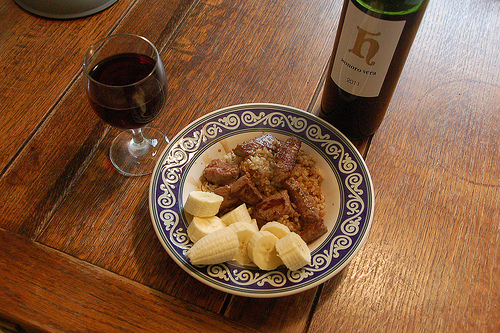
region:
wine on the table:
[335, 3, 417, 136]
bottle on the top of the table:
[338, 8, 437, 146]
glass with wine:
[73, 24, 165, 178]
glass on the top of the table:
[66, 33, 173, 179]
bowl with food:
[157, 109, 367, 299]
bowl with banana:
[166, 85, 364, 326]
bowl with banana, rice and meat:
[183, 99, 371, 295]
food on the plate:
[161, 89, 364, 309]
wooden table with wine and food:
[3, 8, 497, 328]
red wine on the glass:
[70, 36, 185, 185]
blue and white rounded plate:
[161, 108, 376, 308]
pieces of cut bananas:
[167, 202, 309, 275]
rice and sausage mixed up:
[217, 131, 334, 218]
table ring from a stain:
[442, 67, 498, 229]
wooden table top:
[380, 180, 456, 273]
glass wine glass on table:
[68, 40, 167, 197]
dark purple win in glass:
[74, 77, 198, 126]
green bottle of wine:
[333, 0, 391, 146]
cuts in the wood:
[22, 200, 105, 263]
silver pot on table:
[16, 7, 116, 27]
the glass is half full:
[78, 47, 180, 138]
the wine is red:
[71, 40, 188, 148]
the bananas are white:
[172, 175, 309, 271]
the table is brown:
[410, 152, 475, 305]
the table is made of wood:
[418, 140, 485, 278]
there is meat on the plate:
[213, 145, 322, 214]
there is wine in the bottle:
[332, 6, 414, 123]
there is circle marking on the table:
[418, 69, 484, 203]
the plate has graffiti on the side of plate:
[172, 105, 377, 291]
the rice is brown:
[229, 138, 323, 209]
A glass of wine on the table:
[70, 33, 182, 180]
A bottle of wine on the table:
[316, 0, 429, 135]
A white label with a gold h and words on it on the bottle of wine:
[327, 3, 405, 111]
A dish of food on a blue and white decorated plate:
[150, 98, 378, 312]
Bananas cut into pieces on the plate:
[182, 190, 312, 275]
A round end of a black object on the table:
[0, 0, 140, 32]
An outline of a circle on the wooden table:
[408, 60, 498, 191]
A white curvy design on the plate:
[206, 106, 311, 138]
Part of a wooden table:
[0, 18, 90, 330]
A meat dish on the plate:
[211, 136, 331, 217]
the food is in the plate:
[156, 100, 400, 315]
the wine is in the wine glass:
[47, 27, 180, 142]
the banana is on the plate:
[191, 194, 322, 287]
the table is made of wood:
[411, 156, 467, 288]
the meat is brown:
[196, 142, 331, 249]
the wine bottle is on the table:
[327, 1, 444, 180]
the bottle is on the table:
[59, 40, 411, 311]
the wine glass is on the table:
[70, 23, 214, 233]